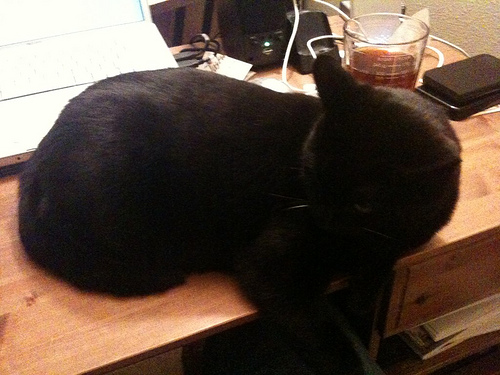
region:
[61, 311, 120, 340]
part of a table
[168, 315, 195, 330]
edge of a table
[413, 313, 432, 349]
part of a drawer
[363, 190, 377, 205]
eye of a cat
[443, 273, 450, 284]
part of a drawer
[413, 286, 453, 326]
edge of drawer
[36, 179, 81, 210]
back of a cat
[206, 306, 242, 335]
part of a table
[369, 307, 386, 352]
part of a drawer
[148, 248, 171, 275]
body of a cat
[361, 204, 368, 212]
eye of a cat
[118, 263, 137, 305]
back of a cat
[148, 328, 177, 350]
side of a table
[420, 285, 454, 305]
edge of a drawer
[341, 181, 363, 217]
head of a cat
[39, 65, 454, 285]
A cat on the desk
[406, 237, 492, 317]
A drawer on the desk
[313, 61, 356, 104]
The ear of the cat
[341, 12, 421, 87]
A glass of a dark beverage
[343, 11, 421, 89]
A glass on a table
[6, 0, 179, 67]
A laptop on a desk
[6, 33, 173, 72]
A keyboard on the laptop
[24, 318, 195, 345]
The desk is made of wood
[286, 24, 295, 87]
A wire by the glass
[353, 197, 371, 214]
The eye of the cat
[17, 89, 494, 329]
Black cat sleeping on desk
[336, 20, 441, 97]
Coffee in a mug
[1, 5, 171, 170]
laptop sitting on desk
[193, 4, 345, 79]
two black phone chargers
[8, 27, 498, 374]
Wooden desk top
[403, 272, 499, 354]
Papers on desk shelf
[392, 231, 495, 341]
Desk top drawer closed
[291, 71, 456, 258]
Black Cats Face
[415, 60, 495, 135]
External hard drives on desk top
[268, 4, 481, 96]
White Cords on desk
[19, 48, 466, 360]
the cat is sitting on the desk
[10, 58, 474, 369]
the cat is black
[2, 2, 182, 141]
a laptop is behind the cat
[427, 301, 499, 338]
there are papers in the draw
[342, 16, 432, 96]
a measuring cup is on the side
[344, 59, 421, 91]
the liquid is in the measuring cup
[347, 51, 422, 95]
the liquid is brown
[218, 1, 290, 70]
the speaker is sitting in the back of the desk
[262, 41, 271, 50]
the green light means the speaker is on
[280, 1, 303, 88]
the wire is white